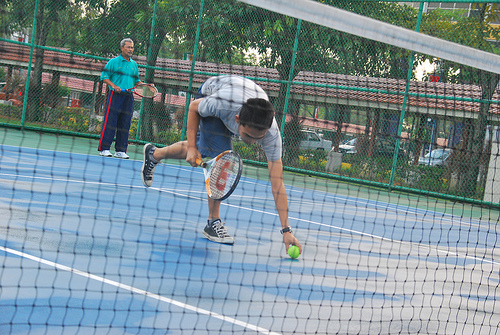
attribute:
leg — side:
[96, 88, 121, 150]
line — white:
[24, 255, 187, 312]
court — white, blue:
[39, 156, 446, 334]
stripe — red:
[91, 87, 115, 152]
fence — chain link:
[0, 2, 493, 138]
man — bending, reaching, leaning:
[120, 49, 339, 286]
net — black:
[1, 14, 486, 334]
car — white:
[294, 116, 330, 161]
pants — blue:
[71, 81, 161, 160]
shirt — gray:
[182, 57, 292, 165]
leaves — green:
[144, 5, 495, 59]